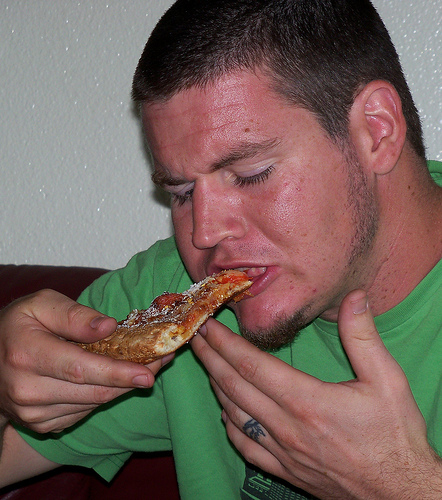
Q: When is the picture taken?
A: While the man is eating.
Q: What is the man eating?
A: Pizza.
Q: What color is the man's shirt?
A: Green.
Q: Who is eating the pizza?
A: The man.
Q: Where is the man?
A: In a restaurant.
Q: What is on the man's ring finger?
A: A tattoo.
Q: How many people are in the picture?
A: One.